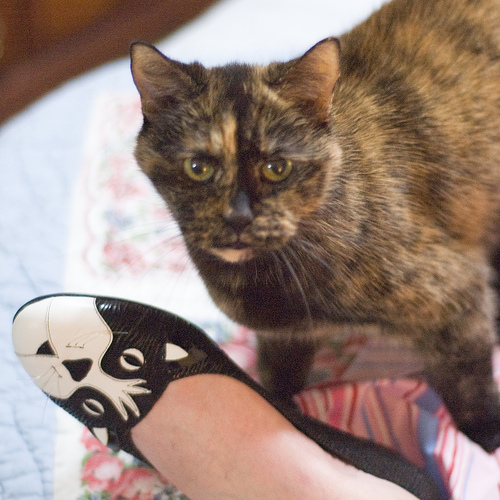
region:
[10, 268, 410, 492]
a black sandal shoe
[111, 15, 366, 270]
head of a cat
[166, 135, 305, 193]
eyes of a cat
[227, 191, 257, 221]
nose of a cat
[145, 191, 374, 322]
whiskers of a cat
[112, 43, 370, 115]
ears of a cat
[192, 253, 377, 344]
neck of a cat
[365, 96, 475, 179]
fur of a cat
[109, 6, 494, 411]
cat sanding on a bed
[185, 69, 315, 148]
forehead of a cat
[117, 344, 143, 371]
white cat eye on shoe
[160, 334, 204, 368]
white and black ear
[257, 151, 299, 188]
yellow eye on brown cat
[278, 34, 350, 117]
brown ear on cat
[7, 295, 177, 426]
black shoe with cat design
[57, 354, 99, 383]
black cat nose on shoe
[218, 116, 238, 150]
patch of tan fur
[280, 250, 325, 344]
long whisker on cat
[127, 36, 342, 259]
dark brown and tan cat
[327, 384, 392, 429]
pink red and blue striped cloth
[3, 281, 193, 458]
Kitty cat face on shoe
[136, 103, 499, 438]
Real cat looking at camera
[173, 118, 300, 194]
Fur different colors on each side of face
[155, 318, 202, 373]
White cat ear on shoe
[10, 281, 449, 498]
Black shoe with cat face on front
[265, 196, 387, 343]
Real cat's whiskers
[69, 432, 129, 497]
One of several flowers on bedspread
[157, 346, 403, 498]
Woman's foot inside shoe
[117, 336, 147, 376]
Black and white eye on shoe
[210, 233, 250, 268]
White fur under cat's mouth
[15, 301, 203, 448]
Woman wearing cat shoe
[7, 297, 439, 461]
The cat shoe is black and white in color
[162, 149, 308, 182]
Cat has green eyes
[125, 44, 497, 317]
Cat is gold, brown and black in color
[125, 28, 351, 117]
Cat has two ears on his head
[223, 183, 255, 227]
Cat's nose is almost completely back in color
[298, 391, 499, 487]
The cover underneat cat is striped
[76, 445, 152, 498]
Flowers is on the woman blanket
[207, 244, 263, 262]
Cat's mouth is flesh color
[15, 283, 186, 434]
cat printed on shoe tp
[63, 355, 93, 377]
black nose of cat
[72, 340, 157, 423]
black and white eyes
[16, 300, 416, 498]
black and white cat shoes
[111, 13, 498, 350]
cat staring straight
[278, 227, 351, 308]
white whiskers of cat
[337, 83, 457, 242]
brown and black fur of cat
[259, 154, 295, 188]
yellow and black eyes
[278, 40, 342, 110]
black and brown ears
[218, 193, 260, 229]
small black nose of cat